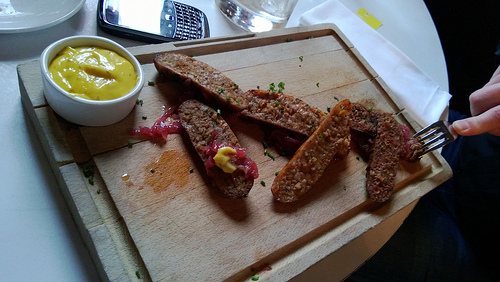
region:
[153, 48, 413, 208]
Slices of cooked sausage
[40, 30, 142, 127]
Small white cup of mustard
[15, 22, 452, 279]
Rectangular light wood cutting board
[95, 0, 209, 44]
Black cellphone with keypad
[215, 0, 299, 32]
Clear glass drinking glass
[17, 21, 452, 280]
Meat and mustard on a cutting board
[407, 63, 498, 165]
Person forking food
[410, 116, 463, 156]
Silver metal fork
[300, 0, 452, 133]
Folded white paper napkin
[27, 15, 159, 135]
The bowl is white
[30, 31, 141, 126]
The bowl is small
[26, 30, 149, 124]
The bowl is round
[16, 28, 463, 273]
The cutting board is wood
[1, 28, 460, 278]
The cutting board is brown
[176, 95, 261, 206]
The meat is brown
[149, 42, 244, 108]
The meat is brown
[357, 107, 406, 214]
The meat is brown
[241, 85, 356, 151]
The meat is brown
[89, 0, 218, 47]
The phone is black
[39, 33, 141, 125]
small white dish filled with yellow sauce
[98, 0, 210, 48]
a black blackberry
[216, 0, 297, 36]
a cup of water on the table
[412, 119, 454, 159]
the tip of a fork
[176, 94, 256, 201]
a slice of bread with toppings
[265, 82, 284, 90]
green cut up chives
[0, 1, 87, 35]
round ceramic white plate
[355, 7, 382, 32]
a yellow square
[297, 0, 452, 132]
a folded white napkin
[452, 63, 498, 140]
someones fingers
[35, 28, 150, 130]
round white ceramic dish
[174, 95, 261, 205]
slice of cooked brown meat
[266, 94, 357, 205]
slice of cooked brown meat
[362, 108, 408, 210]
slice of cooked brown meat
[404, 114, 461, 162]
end of a shiny silver fork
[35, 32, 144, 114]
dish of bright yellow mustard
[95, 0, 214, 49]
shiny black plastic cell phone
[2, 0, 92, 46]
edge of a round white plate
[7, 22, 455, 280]
light brown wooden cutting board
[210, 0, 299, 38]
base of a transparent glass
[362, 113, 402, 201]
a piece of sausage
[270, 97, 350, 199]
a slice of sausage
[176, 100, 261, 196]
a chunk of sausage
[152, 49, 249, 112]
a slice of sausage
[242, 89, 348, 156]
a piece of sausage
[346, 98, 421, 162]
a large piece of sausage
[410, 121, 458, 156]
the tip of a metal fork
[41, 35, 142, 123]
a small dish of yellow mustard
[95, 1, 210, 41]
a cellphone with keyboard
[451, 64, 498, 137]
part of someon'e hand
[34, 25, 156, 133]
tarragon sauce is made with cream, tarragon, and mustard